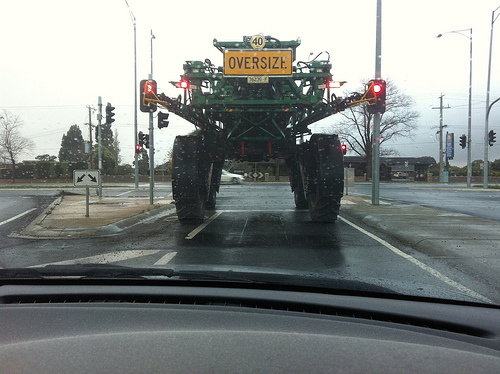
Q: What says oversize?
A: The sign.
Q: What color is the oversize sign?
A: Yellow.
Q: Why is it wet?
A: The rain.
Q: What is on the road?
A: The vehicles.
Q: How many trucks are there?
A: One.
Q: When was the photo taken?
A: Day time.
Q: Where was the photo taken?
A: On the street.